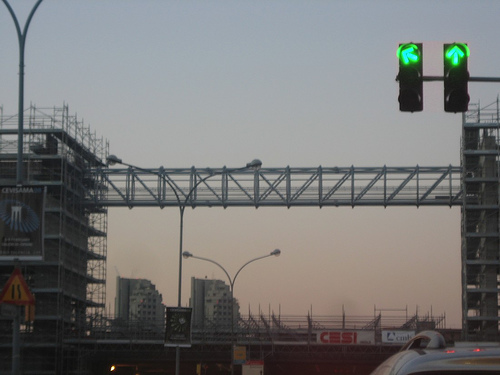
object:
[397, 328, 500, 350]
top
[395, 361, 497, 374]
vehicle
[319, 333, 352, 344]
letters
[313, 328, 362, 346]
sign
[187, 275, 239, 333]
building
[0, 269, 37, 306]
sign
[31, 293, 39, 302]
red border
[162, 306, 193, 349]
sign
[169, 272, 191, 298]
pole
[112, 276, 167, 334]
building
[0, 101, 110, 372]
building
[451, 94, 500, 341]
building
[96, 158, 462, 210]
walkway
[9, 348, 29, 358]
part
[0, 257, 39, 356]
post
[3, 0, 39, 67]
lamp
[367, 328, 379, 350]
edge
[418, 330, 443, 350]
handle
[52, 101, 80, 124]
metal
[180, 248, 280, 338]
street light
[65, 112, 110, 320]
scaffold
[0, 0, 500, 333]
sky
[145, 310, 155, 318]
several windows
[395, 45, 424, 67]
green arrow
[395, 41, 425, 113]
light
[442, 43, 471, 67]
green arrow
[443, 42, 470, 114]
light